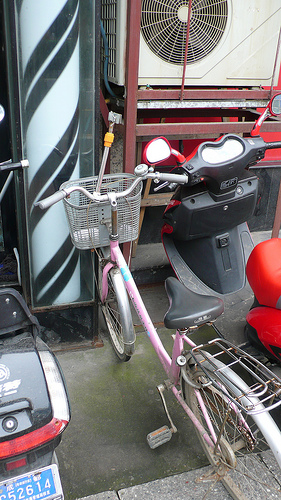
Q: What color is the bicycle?
A: Pink.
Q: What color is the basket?
A: Silver.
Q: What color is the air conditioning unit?
A: White.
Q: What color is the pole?
A: Black and white.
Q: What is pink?
A: Bicycle.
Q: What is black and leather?
A: Bicycle seat.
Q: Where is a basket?
A: On front of bicycle.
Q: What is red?
A: Motorbike.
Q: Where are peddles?
A: On the bicycle.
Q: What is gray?
A: Handles of bicycle.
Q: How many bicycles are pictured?
A: One.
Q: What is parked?
A: Bikes.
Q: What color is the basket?
A: Gray.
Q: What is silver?
A: Handlebars.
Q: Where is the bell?
A: Right handle bar of pink bike.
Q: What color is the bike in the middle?
A: The bike is pink.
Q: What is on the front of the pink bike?
A: A metal basket.